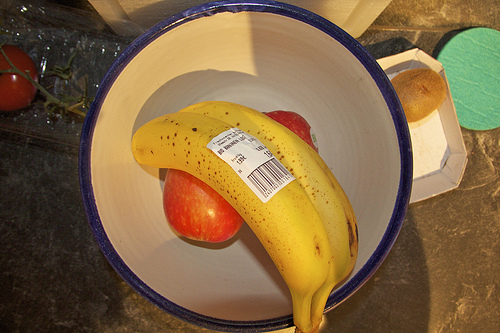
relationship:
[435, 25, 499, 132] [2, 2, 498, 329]
disk on counter